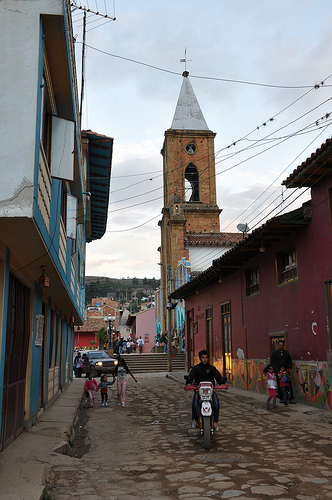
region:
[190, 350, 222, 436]
man on the bike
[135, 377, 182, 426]
the stones are gray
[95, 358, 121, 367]
the headlights are on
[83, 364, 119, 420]
kids on the alley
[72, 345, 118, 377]
people are by the vehicle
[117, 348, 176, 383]
the steps are stone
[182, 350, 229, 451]
young man on motorbike on street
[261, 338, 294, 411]
man and 2 children walking down the street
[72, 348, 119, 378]
light on on an SUV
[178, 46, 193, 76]
weather vane at top of building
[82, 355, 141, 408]
woman and 2 kids walking down the street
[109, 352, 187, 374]
steps from one level to another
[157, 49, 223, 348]
church with a bell tower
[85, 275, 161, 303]
trees on a distant hill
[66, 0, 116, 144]
television antenna on building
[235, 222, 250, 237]
television satellite disk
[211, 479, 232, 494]
a stone on the ground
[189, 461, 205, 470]
a stone on the ground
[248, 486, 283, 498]
a stone on the ground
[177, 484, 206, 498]
a stone on the ground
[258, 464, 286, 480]
a stone on the ground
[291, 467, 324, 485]
a stone on the ground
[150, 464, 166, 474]
a stone on the ground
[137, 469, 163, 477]
a stone on the ground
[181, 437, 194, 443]
a stone on the ground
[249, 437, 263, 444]
a stone on the ground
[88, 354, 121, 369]
Headlights are turned on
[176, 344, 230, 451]
A guy riding a motorbike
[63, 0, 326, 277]
Clouds are in the sky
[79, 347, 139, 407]
Three people are holding hands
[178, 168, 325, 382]
Side of a building is red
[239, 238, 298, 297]
Two windows on a building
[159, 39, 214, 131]
The top of a tower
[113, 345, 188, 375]
A set of steps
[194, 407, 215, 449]
A black rubber tire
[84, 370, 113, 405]
Little girls walking on a street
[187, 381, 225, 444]
A motorcycle on a street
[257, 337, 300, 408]
A man walking with children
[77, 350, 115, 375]
A truck driving on a road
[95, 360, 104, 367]
A headlight on a truck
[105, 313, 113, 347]
Street lights on a pole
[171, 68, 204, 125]
The pointed roof of a tower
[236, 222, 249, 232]
A satellite dish on a building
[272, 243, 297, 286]
Window in the side of a building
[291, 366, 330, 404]
Mural on a wall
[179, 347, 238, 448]
a man on a motorbike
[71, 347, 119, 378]
A vehicle with it's front lights on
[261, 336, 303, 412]
a man walking with two children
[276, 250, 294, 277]
a window on a building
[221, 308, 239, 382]
a window on a building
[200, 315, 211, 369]
indow on a building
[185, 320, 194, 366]
a window on a building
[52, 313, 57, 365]
a window on a building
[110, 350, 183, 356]
a step on a stairway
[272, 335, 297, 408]
a person walking on a street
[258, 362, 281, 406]
a person walking on a street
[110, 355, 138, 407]
a person walking on a street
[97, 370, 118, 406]
a person walking on a street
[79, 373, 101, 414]
a person walking on a street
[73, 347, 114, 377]
a car on a street